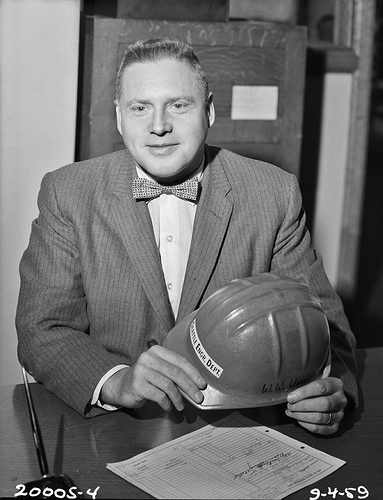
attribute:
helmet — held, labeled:
[167, 250, 286, 385]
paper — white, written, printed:
[70, 395, 312, 497]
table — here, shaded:
[65, 397, 113, 476]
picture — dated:
[12, 22, 335, 485]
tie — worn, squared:
[108, 169, 245, 208]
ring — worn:
[309, 404, 344, 439]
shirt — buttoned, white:
[127, 184, 210, 286]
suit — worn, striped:
[29, 140, 296, 310]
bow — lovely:
[133, 177, 214, 212]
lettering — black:
[215, 434, 312, 495]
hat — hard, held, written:
[180, 294, 300, 374]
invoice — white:
[137, 409, 343, 495]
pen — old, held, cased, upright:
[18, 372, 79, 476]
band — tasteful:
[311, 401, 336, 429]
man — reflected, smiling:
[83, 26, 325, 344]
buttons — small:
[155, 195, 183, 288]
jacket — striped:
[228, 173, 341, 295]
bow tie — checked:
[133, 174, 219, 202]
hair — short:
[119, 22, 274, 92]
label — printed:
[232, 68, 301, 125]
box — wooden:
[232, 25, 331, 145]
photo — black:
[41, 36, 364, 426]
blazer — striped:
[4, 261, 156, 349]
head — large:
[90, 39, 272, 190]